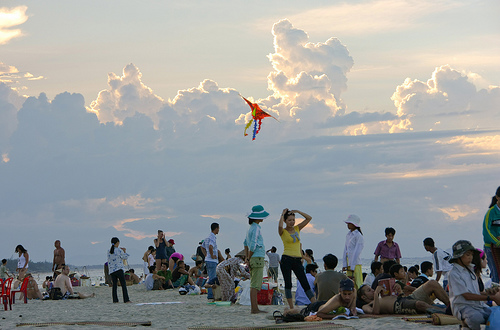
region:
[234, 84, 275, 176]
colorful kite in blue sky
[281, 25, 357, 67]
white fluffy clouds in blue sky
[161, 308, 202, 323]
cement color sand on beach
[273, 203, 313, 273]
woman wearing yellow shirt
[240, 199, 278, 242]
woman wearing teal floppy hat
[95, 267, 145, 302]
woman wearing long black pants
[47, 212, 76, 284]
bald man wearing no shirt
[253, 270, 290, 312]
red and white cooler on sand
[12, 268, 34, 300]
red chair sitting on sand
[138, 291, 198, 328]
white towel laying on cement colored sand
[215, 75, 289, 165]
parasail in sky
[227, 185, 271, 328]
lady wearing blue hat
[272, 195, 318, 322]
lady wearing yellow shirt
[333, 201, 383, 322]
lady wearing white hat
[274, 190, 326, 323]
lady with hands on her head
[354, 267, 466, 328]
guy laying on beach and reading book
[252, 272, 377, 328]
guy laying on beach and reading book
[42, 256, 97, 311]
man with no shirt sitting on beach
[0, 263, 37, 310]
red chairs on beach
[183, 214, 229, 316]
guy standing with hands on his hips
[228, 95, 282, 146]
a colorful flying kite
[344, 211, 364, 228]
a woman's white hat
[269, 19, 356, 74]
a section of white clouds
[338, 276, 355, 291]
a dark baseball cap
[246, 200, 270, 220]
a blue and white hat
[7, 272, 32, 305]
a red chair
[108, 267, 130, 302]
dark women's pants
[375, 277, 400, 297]
a red book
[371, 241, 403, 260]
a purple short sleeved shirt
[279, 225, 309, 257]
a yellow women's shirt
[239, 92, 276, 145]
a kite flying in the sky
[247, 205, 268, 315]
a person in a green hat standing on the beach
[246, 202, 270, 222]
a green hat on a lady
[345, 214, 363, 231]
a white hat on a lady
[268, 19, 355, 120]
clouds in the sky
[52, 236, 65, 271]
a man in swimming trunks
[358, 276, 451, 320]
a man lying down and reading a book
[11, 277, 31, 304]
a red plastic chair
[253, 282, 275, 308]
a red beach bag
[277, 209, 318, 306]
a woman n a yellow shirt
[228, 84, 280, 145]
kite flying in the sky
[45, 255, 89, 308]
man sitting on the beach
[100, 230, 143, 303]
woman standing on the beach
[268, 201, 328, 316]
she is touching her hair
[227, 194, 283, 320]
woman wearing a blue hat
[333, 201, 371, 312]
woman wearing a white hat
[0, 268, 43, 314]
red chairs on the beach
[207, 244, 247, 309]
woman in a dress leaning over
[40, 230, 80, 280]
shirtless man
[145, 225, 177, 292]
a woman in shorts